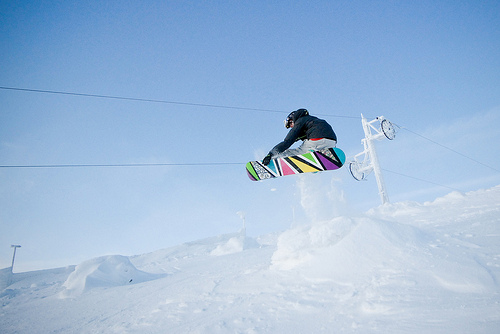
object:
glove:
[261, 156, 271, 167]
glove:
[308, 170, 318, 174]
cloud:
[71, 156, 172, 195]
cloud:
[396, 147, 426, 163]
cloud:
[385, 174, 496, 203]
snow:
[269, 186, 279, 193]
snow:
[296, 176, 322, 225]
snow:
[342, 178, 348, 195]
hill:
[185, 234, 243, 267]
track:
[363, 305, 390, 314]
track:
[371, 292, 392, 302]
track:
[373, 277, 404, 287]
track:
[383, 263, 409, 275]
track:
[429, 241, 443, 251]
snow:
[2, 251, 162, 331]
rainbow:
[274, 154, 341, 175]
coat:
[264, 116, 336, 159]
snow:
[269, 186, 276, 193]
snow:
[324, 176, 335, 186]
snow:
[264, 180, 275, 184]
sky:
[112, 1, 221, 42]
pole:
[10, 244, 21, 275]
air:
[1, 0, 50, 18]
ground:
[3, 319, 61, 331]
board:
[246, 149, 345, 180]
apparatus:
[348, 113, 396, 207]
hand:
[263, 152, 272, 166]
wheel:
[380, 117, 396, 141]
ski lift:
[1, 86, 497, 204]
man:
[243, 103, 350, 181]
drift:
[63, 252, 183, 302]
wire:
[11, 148, 232, 181]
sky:
[6, 0, 112, 38]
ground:
[387, 287, 490, 328]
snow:
[262, 266, 308, 295]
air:
[192, 67, 214, 83]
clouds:
[25, 28, 32, 31]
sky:
[435, 5, 500, 42]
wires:
[8, 80, 162, 104]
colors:
[294, 151, 335, 169]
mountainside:
[29, 190, 475, 324]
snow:
[237, 308, 269, 331]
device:
[344, 103, 404, 205]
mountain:
[209, 235, 260, 258]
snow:
[274, 213, 420, 279]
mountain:
[294, 219, 432, 283]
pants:
[293, 136, 342, 155]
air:
[163, 15, 193, 32]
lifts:
[5, 89, 238, 191]